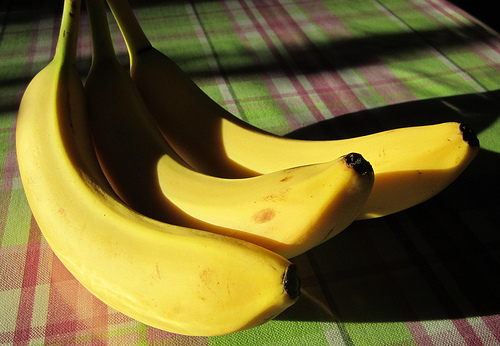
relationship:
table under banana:
[123, 5, 496, 139] [108, 0, 480, 221]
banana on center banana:
[84, 1, 375, 259] [0, 18, 476, 320]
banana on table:
[14, 0, 300, 338] [7, 6, 496, 336]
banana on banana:
[14, 0, 300, 338] [94, 32, 369, 248]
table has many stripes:
[153, 2, 498, 135] [154, 2, 498, 130]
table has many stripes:
[153, 2, 498, 135] [1, 1, 47, 68]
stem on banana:
[43, 2, 154, 57] [84, 1, 375, 259]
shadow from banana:
[312, 225, 462, 346] [59, 14, 376, 244]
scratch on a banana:
[215, 185, 310, 310] [18, 20, 475, 339]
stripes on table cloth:
[212, 312, 352, 346] [259, 31, 390, 71]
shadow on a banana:
[62, 50, 227, 215] [14, 0, 300, 338]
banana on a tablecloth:
[108, 0, 480, 221] [2, 291, 57, 346]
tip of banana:
[340, 147, 372, 185] [88, 115, 361, 242]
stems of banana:
[48, 1, 162, 76] [14, 0, 300, 338]